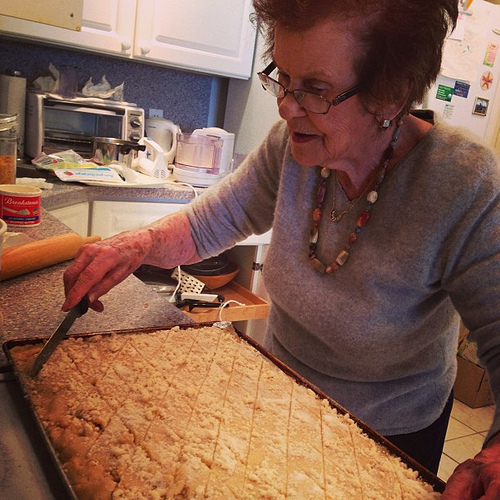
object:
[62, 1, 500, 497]
woman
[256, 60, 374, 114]
eyeglasses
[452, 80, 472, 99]
magnet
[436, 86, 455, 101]
magnet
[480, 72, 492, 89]
magnet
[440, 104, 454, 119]
magnet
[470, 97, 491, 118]
magnet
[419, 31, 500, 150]
refrigerator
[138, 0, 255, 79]
cabinets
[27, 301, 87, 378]
knife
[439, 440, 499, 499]
hand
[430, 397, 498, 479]
floor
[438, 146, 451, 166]
ground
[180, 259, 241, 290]
bowl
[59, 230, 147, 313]
hand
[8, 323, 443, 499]
pastries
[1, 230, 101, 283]
pin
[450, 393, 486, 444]
ground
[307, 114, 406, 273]
necklace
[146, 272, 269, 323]
pullout drawer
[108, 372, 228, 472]
dessert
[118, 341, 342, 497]
dessert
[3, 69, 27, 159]
roll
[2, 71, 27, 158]
paper towels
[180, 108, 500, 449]
shirt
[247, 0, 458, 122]
hair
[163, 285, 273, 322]
shelf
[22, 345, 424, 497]
pastry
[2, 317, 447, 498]
tray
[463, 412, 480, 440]
tile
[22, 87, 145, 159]
toaster oven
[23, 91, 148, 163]
oven